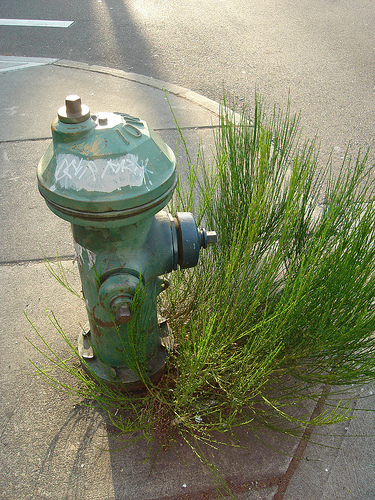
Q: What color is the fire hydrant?
A: Green and white.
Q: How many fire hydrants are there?
A: One.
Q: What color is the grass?
A: Green.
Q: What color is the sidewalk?
A: Gray.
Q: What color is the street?
A: Black.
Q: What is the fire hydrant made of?
A: Metal.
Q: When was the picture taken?
A: Daytime.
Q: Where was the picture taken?
A: Near a fire hydrant.